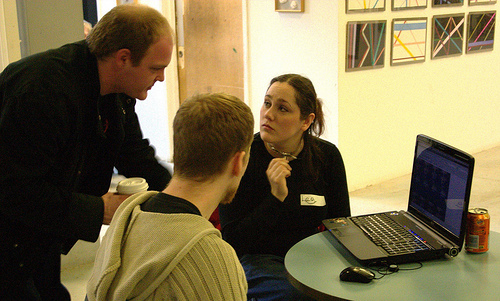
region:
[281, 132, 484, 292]
a laptop computer on a table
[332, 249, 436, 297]
a black computer mouse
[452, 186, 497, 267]
a orange drink can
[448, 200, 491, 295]
a drink can on a table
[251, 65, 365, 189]
a woman touching her necklace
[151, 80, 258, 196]
a man with short hair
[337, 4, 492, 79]
four pictures hanging on the wall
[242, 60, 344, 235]
a woman wearing a black shirt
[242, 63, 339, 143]
a woman with brown hair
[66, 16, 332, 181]
a man and woman looking at each other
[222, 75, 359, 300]
a woman sitting at a table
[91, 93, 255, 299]
the back of a man sitting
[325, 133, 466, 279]
a laptop computer and mouse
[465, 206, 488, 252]
an orange aluminum can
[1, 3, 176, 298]
a man leaning forward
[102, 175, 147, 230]
a cup held by a man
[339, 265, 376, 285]
a computer mouse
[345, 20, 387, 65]
abstract art on the wall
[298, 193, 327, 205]
a white nametag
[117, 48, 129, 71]
a man's ear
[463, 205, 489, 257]
a orange can on the table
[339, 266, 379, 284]
the mouse of the lap top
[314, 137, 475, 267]
a lap top on the table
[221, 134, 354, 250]
a black shirt on a woman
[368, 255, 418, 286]
the cord of a mouse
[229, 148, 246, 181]
the ear on a man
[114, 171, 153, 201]
the lid of a cup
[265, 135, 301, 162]
a necklace on a woman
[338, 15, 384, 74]
a picture on the wall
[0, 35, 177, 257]
a black jacket of a man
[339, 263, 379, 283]
A black, wired computer mouse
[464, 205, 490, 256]
A can of orange soda on the table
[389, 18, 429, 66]
The wall art in the bottom row with a white background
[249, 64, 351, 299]
A girl in black sitting at a table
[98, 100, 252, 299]
A boy in a tan, hooded shirt sitting at the table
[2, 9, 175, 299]
A man in black with coffee who seems to have authority in the situation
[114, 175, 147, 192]
The white lid of the coffee cup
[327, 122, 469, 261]
A black laptop that is powered on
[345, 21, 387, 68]
The left most black wall art in the bottom row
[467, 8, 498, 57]
The right most visible wall art in the bottom row.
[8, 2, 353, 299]
three people talking ina office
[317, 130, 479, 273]
small black laptop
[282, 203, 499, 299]
blue oval table where laptop is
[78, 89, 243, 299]
boy sitting with gray sweter on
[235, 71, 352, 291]
blonde woman sitting with black t-shirt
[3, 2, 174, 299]
old man standing talking with woman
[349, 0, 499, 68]
four pictures hanging in the wall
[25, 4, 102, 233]
open gray door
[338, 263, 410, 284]
small black mouse connected to laptop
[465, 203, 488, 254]
red can of coke